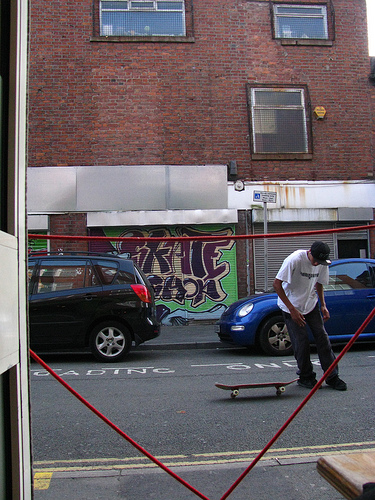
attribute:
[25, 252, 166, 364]
vehicle — dark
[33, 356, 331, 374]
lettering — white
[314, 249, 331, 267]
hat — BLACK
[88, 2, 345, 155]
windows — THREE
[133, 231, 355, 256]
rope — RED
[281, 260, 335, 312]
shirt — T, WHITE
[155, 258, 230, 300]
gate — STEEL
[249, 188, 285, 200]
sign — STREET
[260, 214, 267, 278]
pole — METAL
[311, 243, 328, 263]
cap — BASEBALL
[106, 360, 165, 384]
letters — WHITE, PAINTED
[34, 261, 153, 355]
vehicle — BLACK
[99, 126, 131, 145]
wall — RED, BRICK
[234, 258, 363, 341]
car — BLUE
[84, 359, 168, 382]
lettering — WHITE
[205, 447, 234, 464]
lines — YELLOW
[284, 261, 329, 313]
shirt — WHITE, T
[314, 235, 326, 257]
cap — BLACK, BASEBALL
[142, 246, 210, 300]
graffiti — SKATEBOARDING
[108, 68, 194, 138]
building — BRICK, RED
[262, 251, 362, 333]
car — COMPACT, BLUE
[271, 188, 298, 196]
marks — RUST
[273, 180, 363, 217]
trim — BUILDING